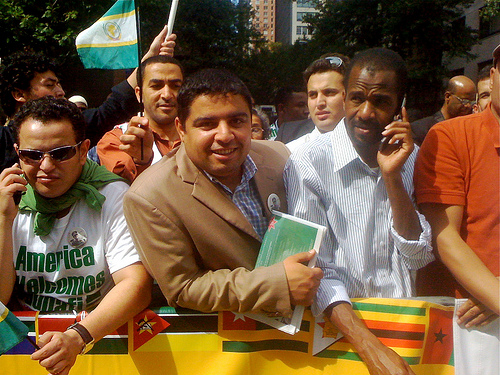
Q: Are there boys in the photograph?
A: No, there are no boys.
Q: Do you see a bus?
A: No, there are no buses.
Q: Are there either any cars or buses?
A: No, there are no buses or cars.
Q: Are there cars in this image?
A: No, there are no cars.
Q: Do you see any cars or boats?
A: No, there are no cars or boats.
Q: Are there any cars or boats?
A: No, there are no cars or boats.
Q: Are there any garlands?
A: No, there are no garlands.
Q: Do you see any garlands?
A: No, there are no garlands.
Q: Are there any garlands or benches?
A: No, there are no garlands or benches.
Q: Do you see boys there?
A: No, there are no boys.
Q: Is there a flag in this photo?
A: Yes, there is a flag.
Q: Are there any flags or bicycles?
A: Yes, there is a flag.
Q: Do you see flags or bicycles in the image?
A: Yes, there is a flag.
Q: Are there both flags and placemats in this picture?
A: No, there is a flag but no placemats.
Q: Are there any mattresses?
A: No, there are no mattresses.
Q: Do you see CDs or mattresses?
A: No, there are no mattresses or cds.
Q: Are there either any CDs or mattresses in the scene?
A: No, there are no mattresses or cds.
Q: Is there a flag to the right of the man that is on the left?
A: Yes, there is a flag to the right of the man.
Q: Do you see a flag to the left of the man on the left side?
A: No, the flag is to the right of the man.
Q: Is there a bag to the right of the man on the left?
A: No, there is a flag to the right of the man.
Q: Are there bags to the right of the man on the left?
A: No, there is a flag to the right of the man.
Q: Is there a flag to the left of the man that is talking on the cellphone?
A: Yes, there is a flag to the left of the man.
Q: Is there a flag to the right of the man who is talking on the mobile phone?
A: No, the flag is to the left of the man.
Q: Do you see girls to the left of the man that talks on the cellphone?
A: No, there is a flag to the left of the man.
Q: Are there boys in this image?
A: No, there are no boys.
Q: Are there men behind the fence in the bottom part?
A: Yes, there is a man behind the fence.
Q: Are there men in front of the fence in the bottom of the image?
A: No, the man is behind the fence.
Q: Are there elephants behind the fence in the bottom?
A: No, there is a man behind the fence.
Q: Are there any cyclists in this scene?
A: No, there are no cyclists.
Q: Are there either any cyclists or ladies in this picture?
A: No, there are no cyclists or ladies.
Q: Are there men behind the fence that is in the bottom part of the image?
A: Yes, there is a man behind the fence.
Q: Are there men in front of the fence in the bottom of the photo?
A: No, the man is behind the fence.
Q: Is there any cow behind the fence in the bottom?
A: No, there is a man behind the fence.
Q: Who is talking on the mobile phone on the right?
A: The man is talking on the cell phone.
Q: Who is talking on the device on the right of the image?
A: The man is talking on the cell phone.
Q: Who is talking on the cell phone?
A: The man is talking on the cell phone.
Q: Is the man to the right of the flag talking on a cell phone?
A: Yes, the man is talking on a cell phone.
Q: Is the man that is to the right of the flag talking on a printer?
A: No, the man is talking on a cell phone.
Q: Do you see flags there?
A: Yes, there is a flag.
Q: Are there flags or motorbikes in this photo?
A: Yes, there is a flag.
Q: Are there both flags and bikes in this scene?
A: No, there is a flag but no bikes.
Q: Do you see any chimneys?
A: No, there are no chimneys.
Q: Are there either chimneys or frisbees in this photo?
A: No, there are no chimneys or frisbees.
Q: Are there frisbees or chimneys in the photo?
A: No, there are no chimneys or frisbees.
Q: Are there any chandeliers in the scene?
A: No, there are no chandeliers.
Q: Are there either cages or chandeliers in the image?
A: No, there are no chandeliers or cages.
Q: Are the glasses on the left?
A: Yes, the glasses are on the left of the image.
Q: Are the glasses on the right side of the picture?
A: No, the glasses are on the left of the image.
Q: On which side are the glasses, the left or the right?
A: The glasses are on the left of the image.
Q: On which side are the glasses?
A: The glasses are on the left of the image.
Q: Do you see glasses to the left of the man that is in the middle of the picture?
A: Yes, there are glasses to the left of the man.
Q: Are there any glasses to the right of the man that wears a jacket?
A: No, the glasses are to the left of the man.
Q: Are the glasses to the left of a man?
A: Yes, the glasses are to the left of a man.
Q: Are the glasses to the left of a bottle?
A: No, the glasses are to the left of a man.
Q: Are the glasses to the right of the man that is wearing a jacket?
A: No, the glasses are to the left of the man.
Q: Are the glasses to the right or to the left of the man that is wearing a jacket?
A: The glasses are to the left of the man.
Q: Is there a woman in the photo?
A: No, there are no women.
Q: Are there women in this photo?
A: No, there are no women.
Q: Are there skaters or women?
A: No, there are no women or skaters.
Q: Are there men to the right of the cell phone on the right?
A: Yes, there is a man to the right of the cell phone.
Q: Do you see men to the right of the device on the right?
A: Yes, there is a man to the right of the cell phone.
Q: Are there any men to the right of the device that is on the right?
A: Yes, there is a man to the right of the cell phone.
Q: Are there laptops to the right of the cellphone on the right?
A: No, there is a man to the right of the cellphone.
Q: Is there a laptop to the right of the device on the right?
A: No, there is a man to the right of the cellphone.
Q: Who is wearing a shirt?
A: The man is wearing a shirt.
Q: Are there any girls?
A: No, there are no girls.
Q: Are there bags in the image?
A: No, there are no bags.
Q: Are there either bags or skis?
A: No, there are no bags or skis.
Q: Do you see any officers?
A: No, there are no officers.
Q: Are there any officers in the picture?
A: No, there are no officers.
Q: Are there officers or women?
A: No, there are no officers or women.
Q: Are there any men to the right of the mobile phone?
A: Yes, there is a man to the right of the mobile phone.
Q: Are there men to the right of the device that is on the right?
A: Yes, there is a man to the right of the mobile phone.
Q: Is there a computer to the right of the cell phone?
A: No, there is a man to the right of the cell phone.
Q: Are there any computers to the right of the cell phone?
A: No, there is a man to the right of the cell phone.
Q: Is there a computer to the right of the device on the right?
A: No, there is a man to the right of the cell phone.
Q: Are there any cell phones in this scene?
A: Yes, there is a cell phone.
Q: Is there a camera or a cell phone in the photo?
A: Yes, there is a cell phone.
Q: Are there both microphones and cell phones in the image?
A: No, there is a cell phone but no microphones.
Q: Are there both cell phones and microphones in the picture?
A: No, there is a cell phone but no microphones.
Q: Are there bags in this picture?
A: No, there are no bags.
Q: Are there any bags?
A: No, there are no bags.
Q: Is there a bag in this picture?
A: No, there are no bags.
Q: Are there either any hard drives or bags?
A: No, there are no bags or hard drives.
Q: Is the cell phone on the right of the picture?
A: Yes, the cell phone is on the right of the image.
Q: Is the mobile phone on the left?
A: No, the mobile phone is on the right of the image.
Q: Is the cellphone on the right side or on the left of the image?
A: The cellphone is on the right of the image.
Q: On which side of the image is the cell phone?
A: The cell phone is on the right of the image.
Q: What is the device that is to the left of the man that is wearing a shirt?
A: The device is a cell phone.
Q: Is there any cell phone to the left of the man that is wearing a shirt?
A: Yes, there is a cell phone to the left of the man.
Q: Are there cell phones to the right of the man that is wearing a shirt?
A: No, the cell phone is to the left of the man.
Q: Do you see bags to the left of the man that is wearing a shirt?
A: No, there is a cell phone to the left of the man.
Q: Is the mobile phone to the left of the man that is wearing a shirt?
A: Yes, the mobile phone is to the left of the man.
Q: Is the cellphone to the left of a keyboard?
A: No, the cellphone is to the left of the man.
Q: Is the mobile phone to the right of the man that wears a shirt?
A: No, the mobile phone is to the left of the man.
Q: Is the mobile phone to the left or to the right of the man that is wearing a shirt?
A: The mobile phone is to the left of the man.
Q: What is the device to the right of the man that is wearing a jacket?
A: The device is a cell phone.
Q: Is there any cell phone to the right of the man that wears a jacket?
A: Yes, there is a cell phone to the right of the man.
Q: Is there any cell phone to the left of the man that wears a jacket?
A: No, the cell phone is to the right of the man.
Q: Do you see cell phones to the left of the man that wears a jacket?
A: No, the cell phone is to the right of the man.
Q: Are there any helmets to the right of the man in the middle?
A: No, there is a cell phone to the right of the man.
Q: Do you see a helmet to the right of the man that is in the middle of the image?
A: No, there is a cell phone to the right of the man.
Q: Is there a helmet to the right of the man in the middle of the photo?
A: No, there is a cell phone to the right of the man.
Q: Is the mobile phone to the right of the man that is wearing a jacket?
A: Yes, the mobile phone is to the right of the man.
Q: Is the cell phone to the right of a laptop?
A: No, the cell phone is to the right of the man.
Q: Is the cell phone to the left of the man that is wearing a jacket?
A: No, the cell phone is to the right of the man.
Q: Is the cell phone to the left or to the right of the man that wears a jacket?
A: The cell phone is to the right of the man.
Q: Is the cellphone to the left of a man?
A: Yes, the cellphone is to the left of a man.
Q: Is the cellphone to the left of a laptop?
A: No, the cellphone is to the left of a man.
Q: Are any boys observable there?
A: No, there are no boys.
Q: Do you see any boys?
A: No, there are no boys.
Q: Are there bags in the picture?
A: No, there are no bags.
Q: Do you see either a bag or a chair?
A: No, there are no bags or chairs.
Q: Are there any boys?
A: No, there are no boys.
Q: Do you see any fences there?
A: Yes, there is a fence.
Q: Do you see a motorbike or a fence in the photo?
A: Yes, there is a fence.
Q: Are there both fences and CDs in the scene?
A: No, there is a fence but no cds.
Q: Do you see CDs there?
A: No, there are no cds.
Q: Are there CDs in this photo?
A: No, there are no cds.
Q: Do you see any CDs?
A: No, there are no cds.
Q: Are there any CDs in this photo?
A: No, there are no cds.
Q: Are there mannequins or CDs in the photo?
A: No, there are no CDs or mannequins.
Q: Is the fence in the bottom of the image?
A: Yes, the fence is in the bottom of the image.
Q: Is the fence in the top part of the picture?
A: No, the fence is in the bottom of the image.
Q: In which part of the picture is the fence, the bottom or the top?
A: The fence is in the bottom of the image.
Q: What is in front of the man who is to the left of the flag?
A: The fence is in front of the man.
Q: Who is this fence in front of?
A: The fence is in front of the man.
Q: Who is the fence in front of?
A: The fence is in front of the man.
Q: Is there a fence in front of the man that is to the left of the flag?
A: Yes, there is a fence in front of the man.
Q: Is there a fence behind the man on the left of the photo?
A: No, the fence is in front of the man.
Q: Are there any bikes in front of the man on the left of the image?
A: No, there is a fence in front of the man.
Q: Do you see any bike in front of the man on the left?
A: No, there is a fence in front of the man.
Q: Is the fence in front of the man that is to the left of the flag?
A: Yes, the fence is in front of the man.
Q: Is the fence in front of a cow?
A: No, the fence is in front of the man.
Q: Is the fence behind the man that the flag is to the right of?
A: No, the fence is in front of the man.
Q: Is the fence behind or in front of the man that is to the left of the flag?
A: The fence is in front of the man.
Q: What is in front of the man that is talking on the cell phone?
A: The fence is in front of the man.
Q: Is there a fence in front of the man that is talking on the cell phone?
A: Yes, there is a fence in front of the man.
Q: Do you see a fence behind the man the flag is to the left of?
A: No, the fence is in front of the man.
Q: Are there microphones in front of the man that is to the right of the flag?
A: No, there is a fence in front of the man.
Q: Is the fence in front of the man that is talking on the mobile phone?
A: Yes, the fence is in front of the man.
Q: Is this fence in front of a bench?
A: No, the fence is in front of the man.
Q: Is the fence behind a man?
A: No, the fence is in front of a man.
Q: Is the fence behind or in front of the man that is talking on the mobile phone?
A: The fence is in front of the man.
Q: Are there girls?
A: No, there are no girls.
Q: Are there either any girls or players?
A: No, there are no girls or players.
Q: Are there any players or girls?
A: No, there are no girls or players.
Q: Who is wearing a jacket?
A: The man is wearing a jacket.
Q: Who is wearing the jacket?
A: The man is wearing a jacket.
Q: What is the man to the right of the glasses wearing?
A: The man is wearing a jacket.